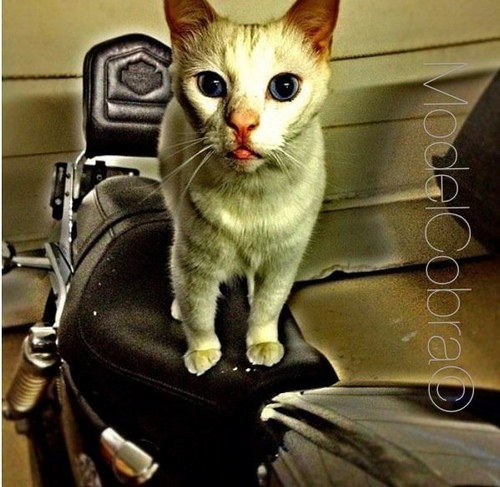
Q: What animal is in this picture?
A: A cat.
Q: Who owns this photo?
A: ModelCobra.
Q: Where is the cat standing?
A: On the motorcycle.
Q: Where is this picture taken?
A: A garage.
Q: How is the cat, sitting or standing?
A: Standing.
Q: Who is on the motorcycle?
A: A cat.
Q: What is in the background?
A: Garage door.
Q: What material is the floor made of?
A: Cement.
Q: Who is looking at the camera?
A: A cat.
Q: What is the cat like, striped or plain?
A: Plain.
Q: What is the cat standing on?
A: Motorcycle.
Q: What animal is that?
A: Cat.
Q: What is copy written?
A: ModelCobra.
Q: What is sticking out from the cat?
A: White whiskers.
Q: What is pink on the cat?
A: Its ears.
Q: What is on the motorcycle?
A: A cat.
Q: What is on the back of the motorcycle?
A: A backrest for a passenger.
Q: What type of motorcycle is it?
A: Harley Davidson.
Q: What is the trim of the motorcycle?
A: Silver.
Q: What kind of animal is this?
A: Cat.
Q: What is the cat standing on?
A: A motorcycle.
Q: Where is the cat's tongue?
A: Poking out of it's mouth.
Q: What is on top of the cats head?
A: Pointy ears.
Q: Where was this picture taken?
A: In the garage.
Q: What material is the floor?
A: Cement.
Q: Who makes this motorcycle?
A: Harley Davidson.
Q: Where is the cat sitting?
A: On the motorcycle.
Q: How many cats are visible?
A: 1.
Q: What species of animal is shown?
A: Cat.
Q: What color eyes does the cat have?
A: Blue.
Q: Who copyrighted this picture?
A: ModelCobra.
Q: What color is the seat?
A: Black.